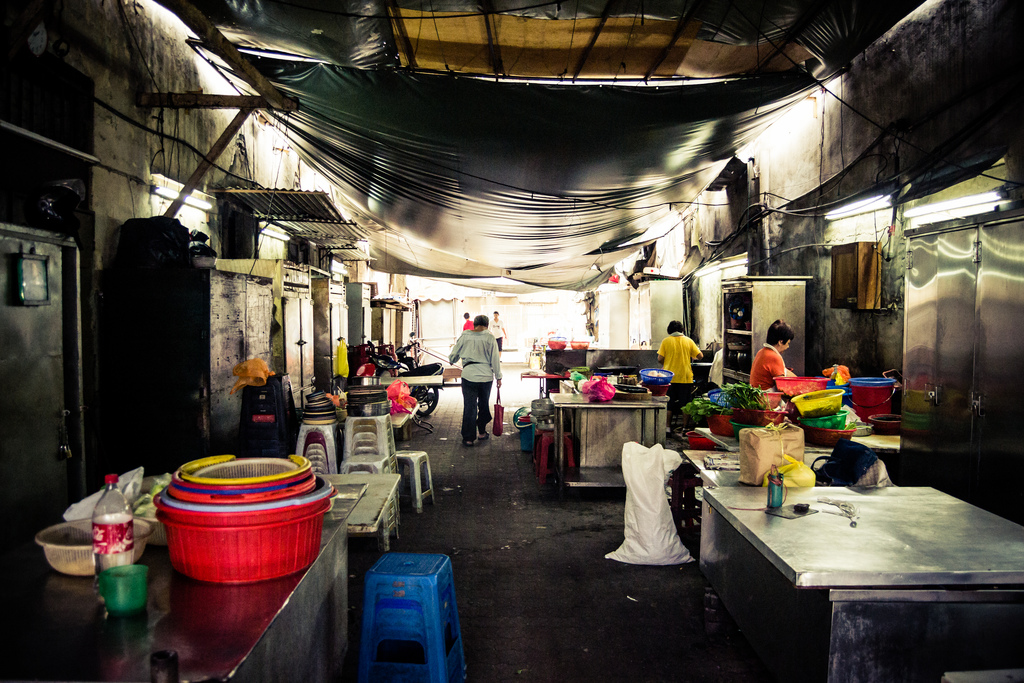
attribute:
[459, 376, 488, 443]
legs — woman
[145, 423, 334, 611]
bowls — stacked, colorful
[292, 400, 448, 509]
stool — white, plastic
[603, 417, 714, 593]
bag — white, large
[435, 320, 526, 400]
shirt — long sleeved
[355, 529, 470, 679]
stools — plastic, blue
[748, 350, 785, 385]
shirt — orange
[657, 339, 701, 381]
shirt — yellow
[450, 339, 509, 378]
shirt — blue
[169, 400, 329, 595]
plastic bowls — bunch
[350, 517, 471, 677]
stools — bunch, blue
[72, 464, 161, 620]
bottle — empty, plastic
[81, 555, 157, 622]
cup — small, green, plastic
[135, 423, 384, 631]
bowls — big, colorful, stacked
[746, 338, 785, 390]
shirt — orange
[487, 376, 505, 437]
bag — red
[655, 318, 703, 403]
person — working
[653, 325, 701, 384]
shirt — yellow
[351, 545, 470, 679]
stool — blue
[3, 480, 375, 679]
table — large, aluminum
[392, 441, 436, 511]
stool — white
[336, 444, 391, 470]
stool — white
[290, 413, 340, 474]
stool — white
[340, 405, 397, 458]
stool — white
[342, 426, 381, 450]
stool — white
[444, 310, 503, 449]
person — walking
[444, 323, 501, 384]
shirt — white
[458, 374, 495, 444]
jeans — bleu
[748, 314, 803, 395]
woman — working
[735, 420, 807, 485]
paper — brown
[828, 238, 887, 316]
cabinet — wooden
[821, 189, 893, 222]
light — fluorescent